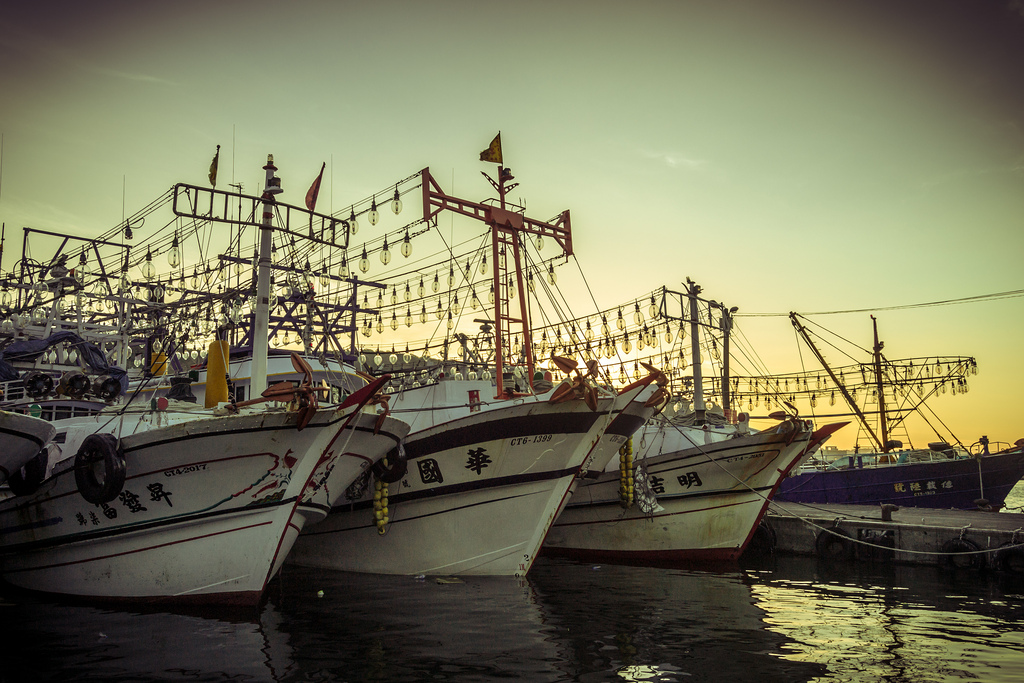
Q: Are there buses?
A: No, there are no buses.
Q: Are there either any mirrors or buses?
A: No, there are no buses or mirrors.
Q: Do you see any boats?
A: Yes, there is a boat.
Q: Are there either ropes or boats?
A: Yes, there is a boat.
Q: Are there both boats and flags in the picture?
A: Yes, there are both a boat and a flag.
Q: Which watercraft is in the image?
A: The watercraft is a boat.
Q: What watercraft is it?
A: The watercraft is a boat.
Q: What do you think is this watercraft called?
A: This is a boat.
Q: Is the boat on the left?
A: Yes, the boat is on the left of the image.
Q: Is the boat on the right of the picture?
A: No, the boat is on the left of the image.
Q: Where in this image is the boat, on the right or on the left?
A: The boat is on the left of the image.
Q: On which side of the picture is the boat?
A: The boat is on the left of the image.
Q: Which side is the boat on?
A: The boat is on the left of the image.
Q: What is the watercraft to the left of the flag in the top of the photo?
A: The watercraft is a boat.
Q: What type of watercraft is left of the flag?
A: The watercraft is a boat.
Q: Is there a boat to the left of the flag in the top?
A: Yes, there is a boat to the left of the flag.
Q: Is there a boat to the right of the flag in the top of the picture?
A: No, the boat is to the left of the flag.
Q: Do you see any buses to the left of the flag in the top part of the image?
A: No, there is a boat to the left of the flag.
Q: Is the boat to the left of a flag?
A: Yes, the boat is to the left of a flag.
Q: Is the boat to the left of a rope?
A: No, the boat is to the left of a flag.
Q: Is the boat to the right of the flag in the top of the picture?
A: No, the boat is to the left of the flag.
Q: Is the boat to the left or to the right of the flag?
A: The boat is to the left of the flag.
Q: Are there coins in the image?
A: No, there are no coins.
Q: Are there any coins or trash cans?
A: No, there are no coins or trash cans.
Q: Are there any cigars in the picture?
A: No, there are no cigars.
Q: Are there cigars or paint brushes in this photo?
A: No, there are no cigars or paint brushes.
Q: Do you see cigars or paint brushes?
A: No, there are no cigars or paint brushes.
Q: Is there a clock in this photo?
A: No, there are no clocks.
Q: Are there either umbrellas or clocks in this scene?
A: No, there are no clocks or umbrellas.